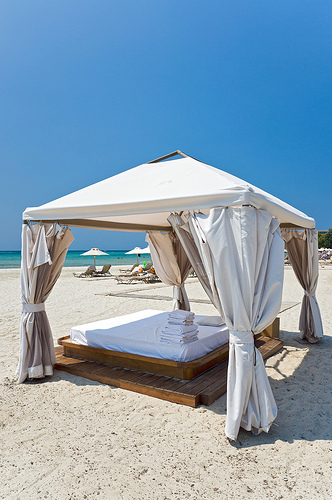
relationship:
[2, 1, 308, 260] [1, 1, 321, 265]
clouds in sky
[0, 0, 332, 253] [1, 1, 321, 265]
clouds in sky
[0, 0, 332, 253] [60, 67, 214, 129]
clouds in blue sky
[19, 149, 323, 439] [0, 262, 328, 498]
tent on beach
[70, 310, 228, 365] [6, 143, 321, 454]
mattress in tent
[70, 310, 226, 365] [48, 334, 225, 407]
mattress on platform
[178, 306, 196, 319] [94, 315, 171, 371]
towel on mattress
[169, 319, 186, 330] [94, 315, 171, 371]
towel on mattress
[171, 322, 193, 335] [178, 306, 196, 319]
towel on towel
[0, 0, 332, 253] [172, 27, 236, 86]
clouds in sky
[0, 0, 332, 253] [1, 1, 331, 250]
clouds in blue sky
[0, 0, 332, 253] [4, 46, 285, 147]
clouds in sky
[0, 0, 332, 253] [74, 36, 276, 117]
clouds in sky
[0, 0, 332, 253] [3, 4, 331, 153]
clouds in sky